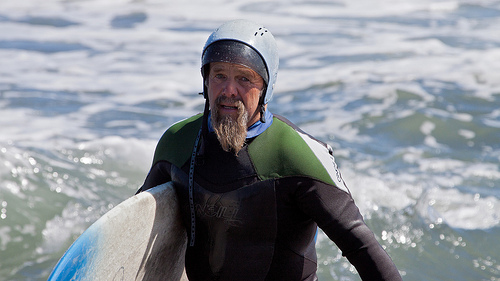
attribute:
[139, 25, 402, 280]
man — old, surfer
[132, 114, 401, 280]
wetsuit — black, green, white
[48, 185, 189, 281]
surfboard — white, blue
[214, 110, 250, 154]
beard — straggly, long, grey, scraggly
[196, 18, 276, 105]
helmet — grey, black, silver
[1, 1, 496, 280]
sea — choppy, blue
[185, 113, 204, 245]
strap — blue, white, black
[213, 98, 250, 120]
mustache — grey, long, gray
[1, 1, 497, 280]
water — blue, green, choppy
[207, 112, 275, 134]
collar — blue